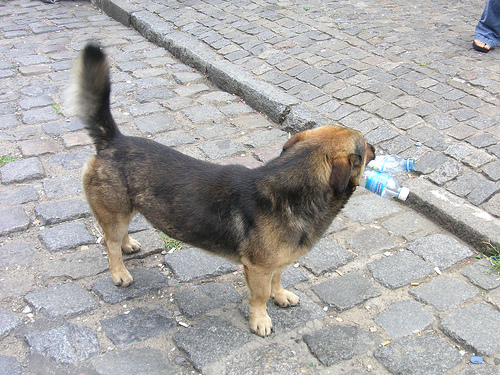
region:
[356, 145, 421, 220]
2 WATER BOTTLES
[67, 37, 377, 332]
BROWN BLACK DOG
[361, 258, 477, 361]
BRICKED PAVED ROAD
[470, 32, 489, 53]
FOOT IN BLACK SANDAL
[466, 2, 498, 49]
PART OF BLUE JEANS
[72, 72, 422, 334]
DOG WITH WATER BOTTLES IN MOUTH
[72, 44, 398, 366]
DOG STANDING IN STREET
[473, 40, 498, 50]
SOMEONES TOES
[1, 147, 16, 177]
PATCH OF GRASS GROWING IN STREET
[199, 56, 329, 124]
CURB TO SIDEWALK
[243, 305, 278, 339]
a front paw on dog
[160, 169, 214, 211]
fur on the dog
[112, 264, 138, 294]
back paw on dog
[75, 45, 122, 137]
tail on the dog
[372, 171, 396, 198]
a clear plastic bottle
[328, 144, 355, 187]
one of the dog's ears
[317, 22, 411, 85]
bricks on the pavement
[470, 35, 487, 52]
person's toes in sandal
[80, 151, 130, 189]
behind of the dog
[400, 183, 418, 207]
a white bottle cap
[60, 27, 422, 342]
a black and orange dog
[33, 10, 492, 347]
dog with bottles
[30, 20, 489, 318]
dog with two bottles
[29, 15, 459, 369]
dog with two bottles in his mouth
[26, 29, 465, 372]
dog on cobblestone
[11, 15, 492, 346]
dog on cobblestone path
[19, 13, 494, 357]
dog out during the day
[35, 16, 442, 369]
dog standing during the day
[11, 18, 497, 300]
dog outside in the sun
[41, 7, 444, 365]
black and orang dog stand up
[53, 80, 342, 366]
dog is black and brown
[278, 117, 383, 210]
the head of a dog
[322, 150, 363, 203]
the ear of a dog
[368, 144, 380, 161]
the nose of a dog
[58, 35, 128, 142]
the tail of a dog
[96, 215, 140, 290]
the hind legs of a dog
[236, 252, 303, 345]
the front legs of a dog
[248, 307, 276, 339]
the paw of a dog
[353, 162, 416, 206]
a plastic water bottle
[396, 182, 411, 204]
a white bottle cap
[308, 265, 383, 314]
a black brick